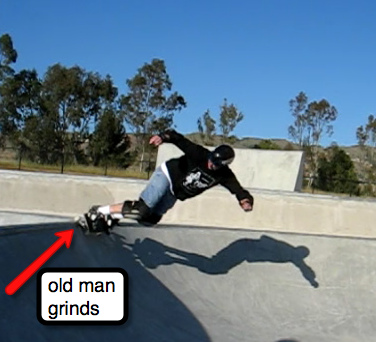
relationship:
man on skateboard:
[101, 127, 250, 220] [80, 203, 90, 233]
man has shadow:
[75, 129, 253, 237] [132, 234, 318, 287]